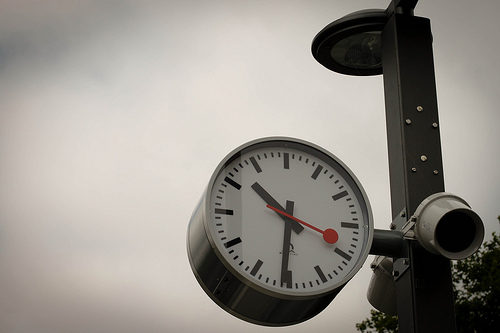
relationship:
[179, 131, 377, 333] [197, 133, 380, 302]
clock has white face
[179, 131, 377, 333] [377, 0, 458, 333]
clock attached to pole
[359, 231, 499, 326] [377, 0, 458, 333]
tree behind pole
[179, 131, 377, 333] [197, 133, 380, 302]
clock has minute increments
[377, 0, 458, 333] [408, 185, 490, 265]
post with camera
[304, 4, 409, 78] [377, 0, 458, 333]
bulb on post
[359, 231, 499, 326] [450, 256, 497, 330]
tree has leaves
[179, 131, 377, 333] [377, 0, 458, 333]
clock hanging off pole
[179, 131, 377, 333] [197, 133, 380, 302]
clock has face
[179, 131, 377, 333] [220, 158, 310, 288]
clock indicating 10:30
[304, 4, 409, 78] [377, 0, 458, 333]
light on top of pole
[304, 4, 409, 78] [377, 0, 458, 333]
light on side of pole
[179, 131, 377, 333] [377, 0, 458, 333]
clock on side pole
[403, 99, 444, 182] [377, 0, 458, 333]
screws are on pole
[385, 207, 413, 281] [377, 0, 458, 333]
screws are on pole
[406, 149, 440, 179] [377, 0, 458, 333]
screws on pole